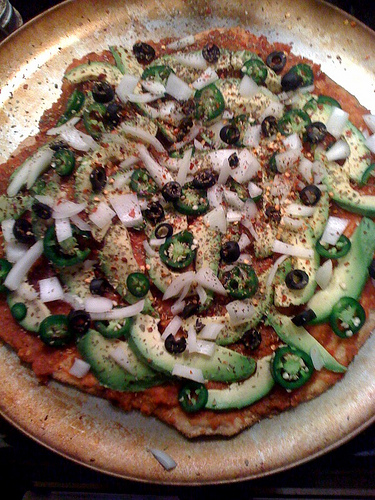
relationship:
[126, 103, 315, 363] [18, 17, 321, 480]
topping` on pizza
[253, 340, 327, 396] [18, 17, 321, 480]
jalapeno on pizza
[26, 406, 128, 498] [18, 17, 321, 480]
crust of pizza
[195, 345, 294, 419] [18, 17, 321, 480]
avocado on pizza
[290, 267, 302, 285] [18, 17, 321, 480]
olive on pizza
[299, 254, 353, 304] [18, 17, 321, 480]
onion on pizza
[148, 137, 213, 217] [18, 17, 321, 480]
seasoning on pizza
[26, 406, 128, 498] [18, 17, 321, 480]
crust on pizza